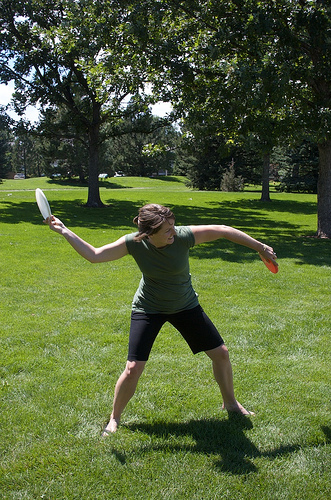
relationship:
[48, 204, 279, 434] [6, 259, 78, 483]
woman on grass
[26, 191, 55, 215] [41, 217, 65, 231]
frisbee in hand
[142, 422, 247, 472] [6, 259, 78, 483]
shadow of woman in grass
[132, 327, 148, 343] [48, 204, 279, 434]
black shorts on woman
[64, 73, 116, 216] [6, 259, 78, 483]
tree trunk in grass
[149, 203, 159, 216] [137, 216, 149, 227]
light on hair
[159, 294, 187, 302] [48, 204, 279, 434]
green shirt on woman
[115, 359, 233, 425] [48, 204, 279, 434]
legs on woman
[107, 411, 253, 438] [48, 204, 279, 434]
feet of woman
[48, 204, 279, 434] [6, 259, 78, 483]
woman standing on grass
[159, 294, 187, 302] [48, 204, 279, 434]
green tank top on woman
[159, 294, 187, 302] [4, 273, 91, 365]
green grass in park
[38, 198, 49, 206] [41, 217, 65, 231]
white frisbee in hand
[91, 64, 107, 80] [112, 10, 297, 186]
green leaves on trees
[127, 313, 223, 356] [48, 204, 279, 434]
shorts on woman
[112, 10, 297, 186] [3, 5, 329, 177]
trees in background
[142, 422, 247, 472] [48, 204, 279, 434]
shadow of woman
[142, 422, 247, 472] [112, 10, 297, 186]
shadow from trees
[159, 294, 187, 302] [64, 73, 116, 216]
green leaf on tree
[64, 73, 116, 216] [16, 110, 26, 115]
tree has leaf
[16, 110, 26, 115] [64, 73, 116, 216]
leaf of tree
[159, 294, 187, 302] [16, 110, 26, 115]
green tree leaf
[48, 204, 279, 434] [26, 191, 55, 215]
woman playing frisbee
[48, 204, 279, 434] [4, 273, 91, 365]
woman at park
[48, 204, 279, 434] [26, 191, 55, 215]
woman holding frisbee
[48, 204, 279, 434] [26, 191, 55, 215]
woman with frisbee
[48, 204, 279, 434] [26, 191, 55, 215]
woman throwing frisbee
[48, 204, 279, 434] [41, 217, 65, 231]
woman with frisbee in hand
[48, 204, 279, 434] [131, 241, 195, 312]
woman wearing green shirt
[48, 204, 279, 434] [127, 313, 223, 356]
woman in black shorts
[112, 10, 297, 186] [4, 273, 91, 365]
trees in park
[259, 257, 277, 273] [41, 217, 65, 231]
red frisbee in hand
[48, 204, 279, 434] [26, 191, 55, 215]
woman holding white frisbee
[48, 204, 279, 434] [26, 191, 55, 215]
woman holding red frisbee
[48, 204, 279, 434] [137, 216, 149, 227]
woman with brown hair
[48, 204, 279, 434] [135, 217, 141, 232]
woman wearing a ponytail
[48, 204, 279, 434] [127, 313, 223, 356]
woman wearing black shorts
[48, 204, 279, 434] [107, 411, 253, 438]
woman wearing flipflops